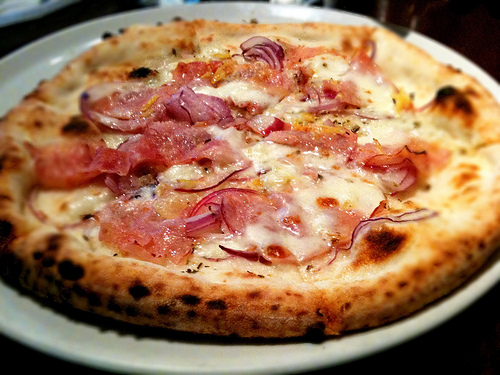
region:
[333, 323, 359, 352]
part of a plate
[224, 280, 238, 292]
edge of a pizza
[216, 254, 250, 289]
top of a pizza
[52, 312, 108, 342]
edge of a plate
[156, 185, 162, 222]
part of an onion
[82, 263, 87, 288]
edge of a pizza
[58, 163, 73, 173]
part of a fruit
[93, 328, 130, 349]
edge of a plate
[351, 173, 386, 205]
part of a pizza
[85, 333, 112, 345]
side of a plate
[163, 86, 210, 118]
ham on the pizza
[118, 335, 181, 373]
the plate is white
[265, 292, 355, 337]
the pizza crust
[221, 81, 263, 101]
cheese on the pizza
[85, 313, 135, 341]
a shadow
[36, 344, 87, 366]
the rim on the plate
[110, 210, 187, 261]
canadian bacon on the pizza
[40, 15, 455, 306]
a small pizza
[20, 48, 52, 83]
a plate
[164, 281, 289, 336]
the crust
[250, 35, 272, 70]
Piece of red onion on pizza.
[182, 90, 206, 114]
Piece of ham on pizza.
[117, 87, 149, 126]
Piece of ham on pizza.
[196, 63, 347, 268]
White cheese melted on pizza.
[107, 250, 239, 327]
Golden brown crust on pizza.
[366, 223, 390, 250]
Burnt cheese on top of pizza.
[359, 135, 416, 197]
Piece of ham on pizza.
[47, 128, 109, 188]
Piece of ham on pizza.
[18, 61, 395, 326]
Pizza sitting on white plate.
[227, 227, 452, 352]
White plate sitting dark counter.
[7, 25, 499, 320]
ham and onion pizza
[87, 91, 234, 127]
cooked ham on pizza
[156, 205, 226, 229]
red onion on pizza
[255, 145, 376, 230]
melted cheese on pizza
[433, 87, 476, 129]
burned cheese on pizza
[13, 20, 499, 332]
cooked pizza on metal tray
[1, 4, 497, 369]
silver metal pizza tray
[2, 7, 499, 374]
pizza tray on table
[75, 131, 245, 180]
cooked meat on pizza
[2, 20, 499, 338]
hot pizza on tray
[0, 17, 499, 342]
A small round pizza with onion, cheese and meat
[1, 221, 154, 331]
Burnt spots on the bottom left crust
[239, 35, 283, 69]
Clump of three layers of onion on the pizza.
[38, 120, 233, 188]
A long piece of bacon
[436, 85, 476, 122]
Very dark burnt crust spot to the right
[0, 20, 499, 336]
Small pizza on a round plate.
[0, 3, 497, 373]
White round shiny plate.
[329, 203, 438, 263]
Thin line of purple onion that is hanging over the crust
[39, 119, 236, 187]
A long piece of a pink bacon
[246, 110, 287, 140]
Small white and purple onion chunk in the very center.